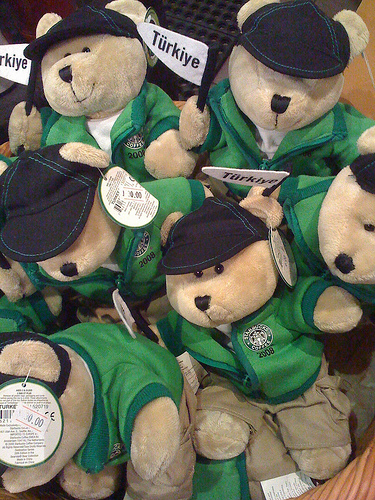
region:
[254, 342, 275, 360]
the year is 2008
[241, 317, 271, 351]
Starbucks logo on a green jacket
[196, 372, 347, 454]
khaki cargo pants on a bear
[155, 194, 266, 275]
navy blue cap with light blue stitching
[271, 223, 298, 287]
tag attached to bear's ear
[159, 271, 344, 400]
a green jacket on a tan bear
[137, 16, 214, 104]
White flag on a black pole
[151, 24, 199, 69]
black letters say Turkey in Turkish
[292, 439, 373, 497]
edge of a basket holding bears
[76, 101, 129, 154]
white shirt worn under a green jacket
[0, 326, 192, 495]
cute teddy bear with jacket and hat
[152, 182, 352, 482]
cute teddy bear with jacket and hat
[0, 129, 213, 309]
cute teddy bear with jacket and hat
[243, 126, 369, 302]
cute teddy bear with jacket and hat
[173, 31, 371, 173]
cute teddy bear with jacket and hat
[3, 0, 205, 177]
cute teddy bear with jacket and hat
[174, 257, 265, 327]
face of cute teddy bear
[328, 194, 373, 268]
face of cute teddy bear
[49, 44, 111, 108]
face of cute teddy bear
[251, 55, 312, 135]
face of cute teddy bear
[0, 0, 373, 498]
the group of stuffed animals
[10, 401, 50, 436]
the white price tag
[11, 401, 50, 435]
the numbers on the price tag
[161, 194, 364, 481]
the stuffed animal wearing a hat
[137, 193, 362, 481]
the hat on the stuffed animal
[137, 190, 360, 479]
the green jacket on the stuffed animal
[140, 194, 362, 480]
the brown pants on the stuffed animal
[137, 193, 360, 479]
the tag hanging from the stuffed animal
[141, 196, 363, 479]
the nose on the stuffed animal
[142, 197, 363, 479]
the eyes on the stuffed animal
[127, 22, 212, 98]
white and black tag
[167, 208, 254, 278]
bear has black hat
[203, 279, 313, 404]
bear has green shirt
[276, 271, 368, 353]
bear has tan paws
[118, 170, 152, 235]
green and white tag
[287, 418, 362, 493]
brown table near bears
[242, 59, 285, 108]
bear has black nose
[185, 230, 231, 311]
bear's eyes are black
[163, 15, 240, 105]
bear holds black flag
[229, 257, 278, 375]
green and black logo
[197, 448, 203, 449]
motorcycle in a field with gravel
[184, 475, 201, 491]
motorcycle in a field with gravel